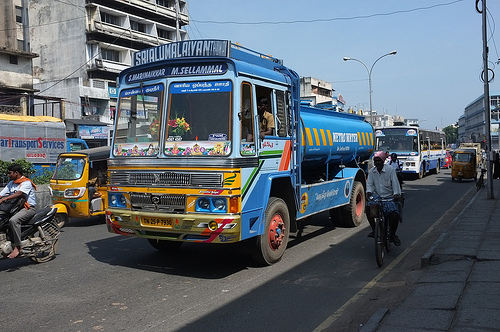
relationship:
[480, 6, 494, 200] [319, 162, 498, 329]
pole on sidewalk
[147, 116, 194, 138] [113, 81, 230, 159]
flowers in windshield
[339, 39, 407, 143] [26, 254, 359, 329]
lights over street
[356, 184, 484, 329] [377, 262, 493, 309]
curb for driveway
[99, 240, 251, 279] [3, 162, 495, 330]
shadow on ground